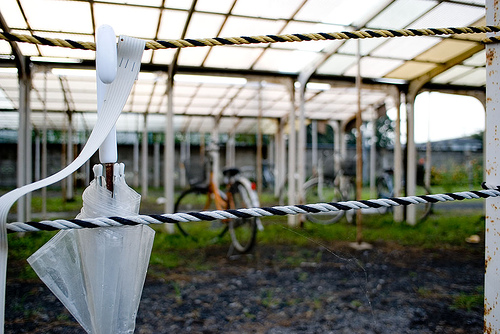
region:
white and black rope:
[20, 183, 495, 251]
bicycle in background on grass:
[162, 166, 277, 237]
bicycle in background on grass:
[278, 150, 340, 230]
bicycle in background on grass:
[384, 146, 476, 236]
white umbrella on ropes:
[63, 137, 128, 327]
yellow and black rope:
[36, 8, 492, 37]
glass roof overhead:
[47, 20, 486, 176]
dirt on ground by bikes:
[147, 255, 366, 330]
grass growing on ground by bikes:
[169, 187, 494, 244]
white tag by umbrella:
[4, 99, 152, 198]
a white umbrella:
[16, 25, 157, 331]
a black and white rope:
[19, 194, 499, 235]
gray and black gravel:
[171, 257, 375, 331]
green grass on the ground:
[306, 218, 430, 258]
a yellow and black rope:
[43, 18, 485, 58]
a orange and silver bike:
[173, 139, 272, 249]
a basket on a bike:
[180, 154, 212, 187]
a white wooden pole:
[158, 81, 184, 216]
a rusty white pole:
[356, 49, 360, 245]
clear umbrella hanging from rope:
[23, 25, 154, 332]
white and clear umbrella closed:
[23, 26, 154, 332]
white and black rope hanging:
[7, 186, 498, 234]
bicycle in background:
[176, 159, 265, 250]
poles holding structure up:
[2, 54, 485, 225]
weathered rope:
[2, 27, 498, 52]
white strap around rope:
[0, 34, 146, 241]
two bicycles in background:
[302, 157, 436, 228]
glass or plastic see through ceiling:
[2, 1, 482, 125]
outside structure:
[4, 3, 497, 202]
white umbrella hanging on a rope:
[25, 27, 157, 332]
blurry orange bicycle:
[171, 135, 266, 255]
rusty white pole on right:
[480, 2, 499, 332]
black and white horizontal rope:
[0, 182, 499, 234]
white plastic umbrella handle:
[91, 21, 121, 166]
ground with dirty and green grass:
[8, 187, 477, 332]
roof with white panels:
[1, 1, 499, 133]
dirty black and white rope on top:
[1, 21, 498, 48]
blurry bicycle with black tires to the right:
[293, 161, 437, 224]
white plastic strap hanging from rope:
[0, 32, 148, 332]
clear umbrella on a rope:
[27, 18, 159, 330]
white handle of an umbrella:
[88, 19, 127, 169]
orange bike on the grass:
[161, 136, 266, 255]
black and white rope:
[3, 181, 497, 231]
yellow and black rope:
[0, 18, 499, 63]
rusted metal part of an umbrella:
[103, 160, 115, 190]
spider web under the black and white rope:
[268, 215, 482, 327]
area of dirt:
[10, 238, 487, 332]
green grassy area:
[7, 182, 498, 257]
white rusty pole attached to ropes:
[479, 0, 499, 332]